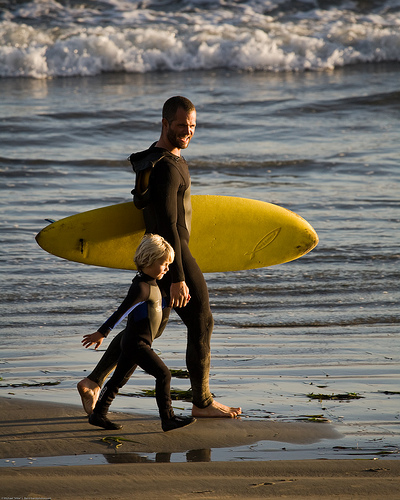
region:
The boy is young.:
[97, 235, 186, 402]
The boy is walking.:
[68, 223, 212, 450]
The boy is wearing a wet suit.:
[86, 221, 198, 460]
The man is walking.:
[90, 77, 258, 423]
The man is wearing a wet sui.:
[92, 91, 248, 423]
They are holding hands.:
[76, 77, 264, 451]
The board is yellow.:
[36, 199, 321, 300]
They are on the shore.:
[57, 55, 394, 461]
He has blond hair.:
[124, 223, 193, 301]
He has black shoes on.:
[73, 387, 217, 443]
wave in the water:
[0, 0, 398, 74]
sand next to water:
[1, 394, 340, 457]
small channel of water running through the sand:
[2, 439, 356, 466]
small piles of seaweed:
[308, 393, 362, 402]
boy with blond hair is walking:
[79, 234, 197, 432]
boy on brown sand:
[74, 233, 196, 433]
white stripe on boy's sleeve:
[113, 297, 146, 329]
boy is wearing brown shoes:
[161, 414, 199, 431]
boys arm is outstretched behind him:
[80, 284, 150, 350]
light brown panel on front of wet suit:
[148, 284, 164, 344]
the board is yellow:
[215, 196, 301, 272]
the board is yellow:
[230, 153, 298, 347]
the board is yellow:
[129, 181, 313, 303]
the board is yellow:
[153, 173, 253, 285]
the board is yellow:
[184, 187, 328, 365]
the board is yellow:
[192, 162, 293, 231]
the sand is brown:
[205, 408, 288, 445]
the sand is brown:
[210, 418, 247, 442]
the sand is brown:
[202, 437, 271, 469]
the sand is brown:
[218, 462, 268, 490]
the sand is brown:
[229, 448, 307, 497]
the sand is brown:
[246, 465, 291, 486]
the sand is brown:
[240, 457, 283, 499]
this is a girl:
[90, 245, 169, 473]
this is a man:
[144, 96, 200, 219]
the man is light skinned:
[182, 111, 192, 119]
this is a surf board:
[198, 189, 294, 259]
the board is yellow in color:
[215, 221, 244, 251]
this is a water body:
[335, 132, 383, 297]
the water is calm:
[300, 285, 389, 337]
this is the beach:
[180, 463, 271, 499]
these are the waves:
[60, 27, 230, 53]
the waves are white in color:
[147, 26, 211, 46]